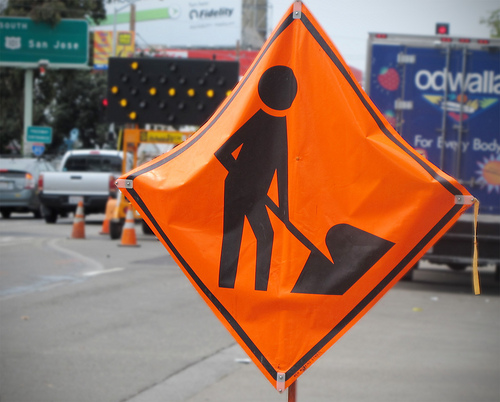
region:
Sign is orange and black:
[106, 0, 492, 399]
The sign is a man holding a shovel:
[213, 172, 387, 298]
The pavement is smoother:
[85, 305, 182, 354]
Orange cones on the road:
[72, 209, 192, 275]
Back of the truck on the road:
[367, 32, 495, 224]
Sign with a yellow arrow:
[101, 44, 276, 128]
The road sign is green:
[0, 23, 97, 75]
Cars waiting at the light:
[6, 130, 147, 231]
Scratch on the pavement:
[33, 222, 115, 293]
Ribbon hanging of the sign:
[450, 195, 497, 327]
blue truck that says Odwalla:
[366, 31, 498, 221]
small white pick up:
[36, 147, 133, 222]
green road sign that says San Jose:
[1, 15, 91, 67]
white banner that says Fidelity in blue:
[179, 3, 242, 28]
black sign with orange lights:
[108, 56, 240, 123]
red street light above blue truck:
[434, 22, 449, 34]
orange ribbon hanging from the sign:
[471, 200, 479, 294]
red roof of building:
[153, 43, 361, 90]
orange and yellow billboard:
[90, 29, 132, 64]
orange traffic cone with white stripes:
[118, 202, 140, 247]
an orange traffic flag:
[120, 9, 481, 386]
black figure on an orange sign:
[198, 57, 317, 293]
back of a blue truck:
[361, 31, 498, 291]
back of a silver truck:
[34, 142, 146, 217]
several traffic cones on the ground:
[70, 204, 147, 251]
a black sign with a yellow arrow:
[105, 48, 240, 133]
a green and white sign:
[0, 13, 95, 71]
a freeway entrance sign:
[20, 126, 57, 144]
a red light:
[426, 20, 455, 36]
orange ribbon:
[464, 194, 486, 300]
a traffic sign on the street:
[107, 1, 478, 391]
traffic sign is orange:
[103, 0, 479, 395]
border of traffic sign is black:
[110, 3, 482, 394]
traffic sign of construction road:
[108, 1, 478, 389]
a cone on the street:
[112, 199, 140, 254]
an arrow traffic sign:
[100, 48, 244, 133]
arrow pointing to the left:
[94, 58, 238, 135]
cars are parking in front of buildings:
[2, 132, 133, 214]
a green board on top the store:
[0, 11, 102, 76]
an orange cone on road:
[67, 191, 94, 251]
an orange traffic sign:
[107, 6, 490, 388]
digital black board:
[102, 50, 252, 134]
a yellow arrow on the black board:
[104, 56, 236, 135]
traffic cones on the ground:
[66, 195, 156, 261]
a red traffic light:
[432, 20, 453, 37]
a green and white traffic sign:
[0, 16, 104, 71]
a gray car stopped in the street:
[0, 147, 54, 230]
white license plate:
[62, 191, 89, 207]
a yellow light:
[167, 85, 178, 97]